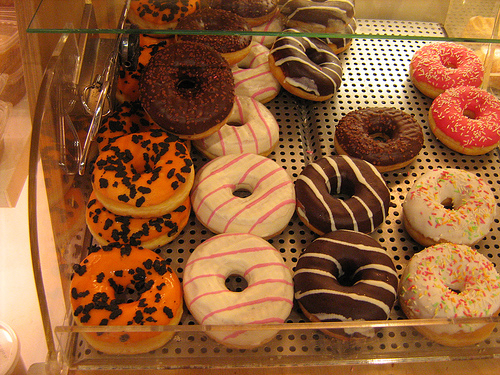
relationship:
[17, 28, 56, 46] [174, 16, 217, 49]
plate on table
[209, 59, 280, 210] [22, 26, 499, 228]
doughnuts in a display case